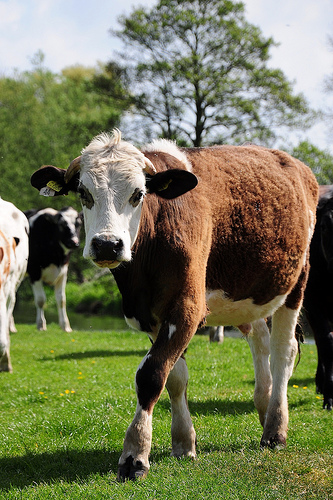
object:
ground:
[30, 387, 114, 464]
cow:
[30, 127, 318, 483]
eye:
[129, 185, 147, 206]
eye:
[76, 183, 95, 210]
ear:
[145, 168, 199, 200]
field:
[5, 307, 329, 497]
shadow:
[3, 433, 116, 491]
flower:
[54, 384, 79, 401]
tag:
[39, 180, 57, 195]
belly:
[206, 300, 278, 328]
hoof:
[117, 455, 150, 484]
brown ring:
[129, 187, 144, 208]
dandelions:
[247, 440, 328, 495]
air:
[23, 161, 78, 202]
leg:
[118, 290, 205, 468]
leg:
[165, 349, 196, 460]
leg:
[260, 306, 299, 442]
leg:
[245, 318, 273, 429]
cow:
[27, 207, 83, 333]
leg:
[55, 276, 71, 332]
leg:
[30, 279, 46, 331]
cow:
[0, 195, 29, 371]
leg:
[0, 293, 12, 370]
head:
[30, 127, 162, 268]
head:
[53, 207, 84, 250]